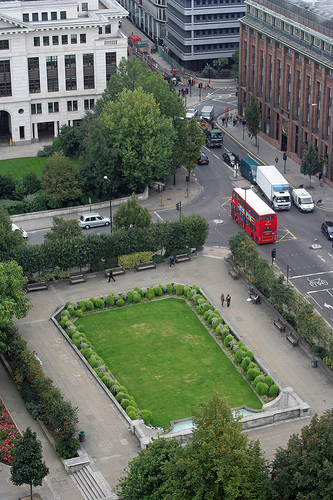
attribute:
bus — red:
[228, 186, 279, 247]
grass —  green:
[60, 275, 317, 460]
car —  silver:
[75, 211, 111, 230]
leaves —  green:
[162, 392, 268, 499]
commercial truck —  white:
[256, 165, 292, 211]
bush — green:
[146, 288, 154, 297]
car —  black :
[317, 217, 332, 247]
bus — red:
[232, 187, 276, 244]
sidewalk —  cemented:
[9, 178, 205, 222]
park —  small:
[0, 212, 331, 498]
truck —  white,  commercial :
[259, 167, 291, 209]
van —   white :
[289, 185, 311, 211]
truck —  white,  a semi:
[250, 152, 292, 212]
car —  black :
[197, 149, 209, 166]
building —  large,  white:
[3, 1, 133, 143]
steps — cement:
[57, 450, 119, 497]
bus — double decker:
[206, 154, 290, 253]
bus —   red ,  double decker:
[206, 170, 296, 240]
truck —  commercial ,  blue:
[237, 155, 255, 183]